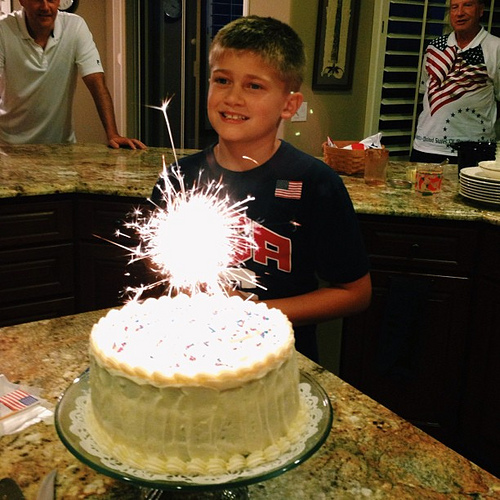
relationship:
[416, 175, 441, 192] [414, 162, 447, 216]
hot peppers on glass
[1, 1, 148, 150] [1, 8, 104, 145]
man wearing polo shirt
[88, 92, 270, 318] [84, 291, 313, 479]
sparkler candle on top of cake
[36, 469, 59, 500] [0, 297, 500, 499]
knife on countertop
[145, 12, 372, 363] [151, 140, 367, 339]
child wearing t-shirt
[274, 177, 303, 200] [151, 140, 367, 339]
flag on t-shirt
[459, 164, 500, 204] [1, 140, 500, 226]
plates on countertop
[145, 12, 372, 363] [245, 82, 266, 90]
child has eye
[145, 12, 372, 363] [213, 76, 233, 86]
child has eye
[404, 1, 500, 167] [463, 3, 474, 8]
man has eye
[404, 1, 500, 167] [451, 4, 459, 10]
man has eye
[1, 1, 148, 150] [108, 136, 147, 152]
man has hand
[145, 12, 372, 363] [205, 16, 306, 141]
child has head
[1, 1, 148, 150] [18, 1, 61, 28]
man has head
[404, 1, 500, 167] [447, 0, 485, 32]
man has head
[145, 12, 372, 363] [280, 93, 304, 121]
child has ear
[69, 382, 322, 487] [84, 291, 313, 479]
doily under cake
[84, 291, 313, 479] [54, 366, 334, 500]
cake on cake stand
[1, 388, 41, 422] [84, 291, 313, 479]
american flag next to cake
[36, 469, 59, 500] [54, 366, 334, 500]
knife under cake stand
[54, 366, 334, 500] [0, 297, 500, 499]
cake stand on countertop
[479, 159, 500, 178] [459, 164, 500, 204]
bowl on plates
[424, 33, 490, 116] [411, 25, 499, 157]
flag graphic on polo shirt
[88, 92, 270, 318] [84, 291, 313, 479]
sparkler candle on cake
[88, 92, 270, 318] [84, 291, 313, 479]
sparkler candle over cake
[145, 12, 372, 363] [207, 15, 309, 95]
child has hair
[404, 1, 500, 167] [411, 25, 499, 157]
man wearing polo shirt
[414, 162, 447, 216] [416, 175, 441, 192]
glass with peppers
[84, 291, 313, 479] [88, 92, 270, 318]
cake has sparkler candle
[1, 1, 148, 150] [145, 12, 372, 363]
man watching child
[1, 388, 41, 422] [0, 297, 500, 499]
american flag on countertop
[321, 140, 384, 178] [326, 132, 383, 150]
basket has snacks